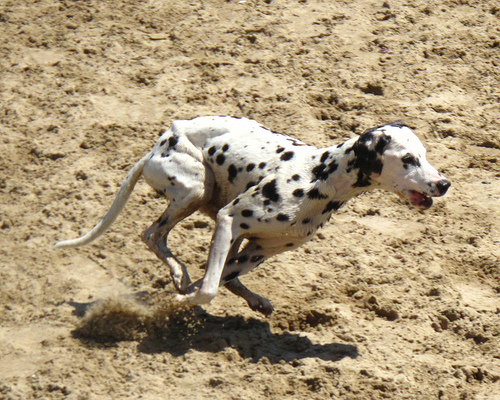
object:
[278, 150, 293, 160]
spot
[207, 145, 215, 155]
spot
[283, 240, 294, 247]
spot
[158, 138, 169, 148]
spot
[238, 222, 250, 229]
spot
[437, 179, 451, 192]
nose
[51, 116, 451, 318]
dalmation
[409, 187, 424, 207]
tongue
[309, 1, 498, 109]
beach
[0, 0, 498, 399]
ground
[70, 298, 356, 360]
shadow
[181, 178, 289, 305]
leg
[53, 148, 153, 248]
tail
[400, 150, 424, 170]
spot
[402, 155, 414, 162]
eye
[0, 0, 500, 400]
dirt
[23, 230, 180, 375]
beach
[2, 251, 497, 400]
sand field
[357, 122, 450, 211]
head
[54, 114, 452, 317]
dog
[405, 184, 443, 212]
mouth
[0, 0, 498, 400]
sand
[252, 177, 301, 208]
black spots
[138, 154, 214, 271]
leg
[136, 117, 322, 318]
body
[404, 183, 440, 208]
mouth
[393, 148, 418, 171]
spot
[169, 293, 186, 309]
paw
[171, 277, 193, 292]
paw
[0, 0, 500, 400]
footprints